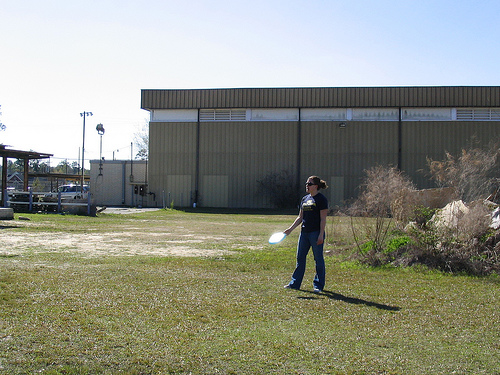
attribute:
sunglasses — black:
[304, 180, 315, 186]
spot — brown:
[1, 228, 250, 260]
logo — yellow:
[301, 199, 315, 207]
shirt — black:
[298, 191, 330, 233]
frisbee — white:
[268, 230, 285, 246]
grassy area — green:
[0, 210, 499, 373]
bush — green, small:
[380, 229, 413, 253]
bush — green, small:
[345, 235, 372, 259]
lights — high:
[75, 106, 95, 118]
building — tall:
[138, 81, 498, 215]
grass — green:
[2, 205, 498, 373]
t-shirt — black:
[298, 192, 328, 232]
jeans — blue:
[288, 228, 329, 288]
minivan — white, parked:
[41, 183, 88, 203]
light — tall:
[75, 106, 95, 198]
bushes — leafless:
[327, 142, 498, 272]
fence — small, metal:
[2, 183, 97, 215]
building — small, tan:
[85, 155, 145, 209]